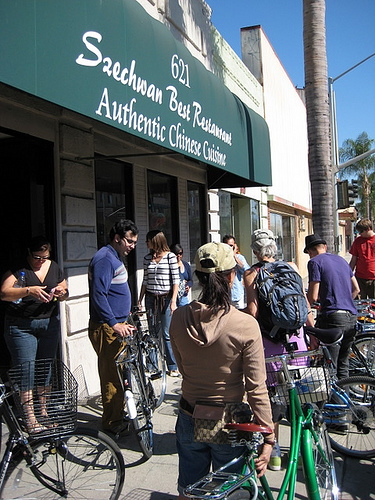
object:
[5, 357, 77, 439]
basket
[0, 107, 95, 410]
wall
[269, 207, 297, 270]
window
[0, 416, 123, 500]
hand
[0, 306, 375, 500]
ground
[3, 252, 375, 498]
pavement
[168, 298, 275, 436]
brown jacket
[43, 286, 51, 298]
phone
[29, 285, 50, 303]
hand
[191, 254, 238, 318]
hair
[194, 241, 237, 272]
cap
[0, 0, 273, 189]
awning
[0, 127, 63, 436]
doorway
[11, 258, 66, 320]
tee shirt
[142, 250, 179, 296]
cow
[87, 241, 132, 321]
shirt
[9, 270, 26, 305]
water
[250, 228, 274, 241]
cap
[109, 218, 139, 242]
hair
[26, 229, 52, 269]
hair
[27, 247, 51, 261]
sunglasses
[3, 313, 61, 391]
capris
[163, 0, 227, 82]
shadow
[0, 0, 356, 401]
building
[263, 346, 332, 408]
basket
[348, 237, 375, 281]
shirt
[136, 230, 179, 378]
woman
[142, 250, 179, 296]
shirt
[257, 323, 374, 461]
bicycle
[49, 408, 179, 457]
shadow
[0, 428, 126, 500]
bicycle tire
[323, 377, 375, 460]
bicycle tire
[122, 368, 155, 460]
bicycle tire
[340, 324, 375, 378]
bicycle tire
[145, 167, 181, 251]
windows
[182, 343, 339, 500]
bicycle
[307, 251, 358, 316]
purple shirt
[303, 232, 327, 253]
black hat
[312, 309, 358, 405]
black jeans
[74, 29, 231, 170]
letters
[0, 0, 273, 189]
sign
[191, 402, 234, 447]
bag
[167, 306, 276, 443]
back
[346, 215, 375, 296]
man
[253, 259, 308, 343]
backpack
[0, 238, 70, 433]
cyclist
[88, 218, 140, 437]
cyclist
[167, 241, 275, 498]
cyclist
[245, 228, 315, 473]
cyclist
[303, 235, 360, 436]
cyclist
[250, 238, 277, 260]
hair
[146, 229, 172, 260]
hair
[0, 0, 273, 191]
restaurant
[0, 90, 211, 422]
storefront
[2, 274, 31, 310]
arm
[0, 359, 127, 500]
bicycle